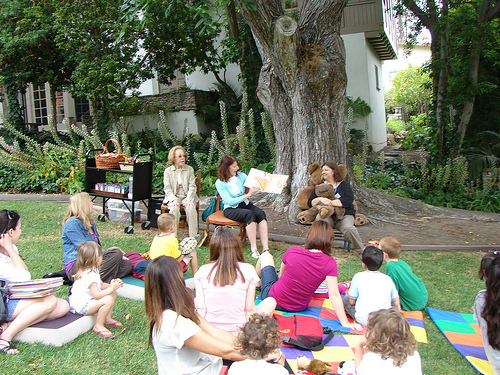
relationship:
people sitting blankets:
[2, 190, 481, 361] [421, 304, 479, 366]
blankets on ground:
[421, 304, 479, 366] [5, 201, 467, 372]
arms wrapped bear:
[304, 192, 354, 212] [295, 164, 338, 245]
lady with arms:
[311, 159, 367, 251] [304, 192, 354, 212]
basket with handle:
[95, 139, 123, 167] [98, 138, 119, 148]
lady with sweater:
[214, 152, 272, 257] [214, 181, 249, 201]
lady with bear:
[313, 165, 366, 245] [316, 185, 332, 221]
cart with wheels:
[82, 148, 154, 234] [94, 216, 164, 237]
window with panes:
[11, 86, 61, 136] [29, 83, 54, 123]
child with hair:
[228, 314, 275, 372] [246, 318, 271, 352]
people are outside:
[4, 147, 445, 370] [3, 4, 484, 367]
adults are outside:
[146, 226, 344, 372] [3, 4, 484, 367]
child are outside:
[228, 314, 292, 374] [3, 4, 484, 367]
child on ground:
[228, 314, 292, 374] [13, 205, 158, 365]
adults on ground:
[3, 180, 133, 312] [39, 209, 145, 372]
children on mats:
[340, 306, 422, 373] [277, 311, 362, 368]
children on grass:
[130, 247, 415, 372] [55, 337, 151, 372]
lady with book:
[203, 156, 283, 252] [241, 169, 296, 208]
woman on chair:
[156, 142, 205, 243] [196, 173, 204, 233]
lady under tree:
[311, 159, 367, 251] [240, 3, 354, 169]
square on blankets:
[424, 310, 458, 325] [421, 304, 500, 374]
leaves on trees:
[5, 4, 228, 92] [0, 1, 267, 167]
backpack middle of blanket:
[270, 313, 335, 352] [254, 283, 427, 374]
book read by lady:
[244, 163, 287, 205] [208, 147, 287, 262]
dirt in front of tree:
[374, 196, 498, 236] [235, 5, 496, 267]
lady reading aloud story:
[214, 152, 272, 257] [240, 167, 289, 199]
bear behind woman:
[303, 155, 349, 226] [307, 159, 367, 240]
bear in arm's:
[318, 181, 347, 224] [307, 195, 348, 206]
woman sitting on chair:
[160, 145, 202, 244] [150, 193, 215, 224]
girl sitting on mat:
[274, 220, 354, 331] [305, 300, 364, 346]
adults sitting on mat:
[192, 225, 280, 336] [270, 310, 300, 323]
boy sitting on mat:
[358, 242, 388, 326] [339, 313, 377, 333]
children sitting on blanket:
[340, 306, 422, 373] [254, 283, 427, 374]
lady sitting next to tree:
[311, 159, 367, 251] [240, 3, 424, 261]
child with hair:
[69, 240, 124, 338] [69, 239, 101, 267]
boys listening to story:
[357, 223, 417, 307] [242, 160, 292, 195]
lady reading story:
[214, 152, 272, 257] [242, 166, 291, 190]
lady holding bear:
[311, 159, 367, 251] [308, 179, 343, 216]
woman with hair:
[0, 206, 83, 344] [0, 202, 19, 229]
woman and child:
[0, 206, 73, 356] [69, 240, 124, 338]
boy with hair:
[145, 211, 199, 276] [154, 209, 176, 230]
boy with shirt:
[145, 211, 199, 276] [142, 230, 188, 258]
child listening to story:
[70, 240, 125, 341] [248, 166, 290, 196]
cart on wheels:
[82, 144, 157, 234] [96, 212, 152, 236]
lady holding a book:
[214, 152, 272, 257] [246, 166, 291, 194]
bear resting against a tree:
[305, 181, 344, 222] [228, 2, 350, 215]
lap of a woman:
[6, 298, 70, 313] [0, 206, 73, 356]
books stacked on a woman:
[13, 275, 62, 295] [0, 206, 73, 356]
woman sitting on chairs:
[160, 145, 202, 244] [156, 210, 338, 245]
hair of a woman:
[306, 220, 335, 240] [270, 224, 361, 337]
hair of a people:
[144, 254, 201, 334] [142, 253, 283, 373]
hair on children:
[237, 310, 425, 364] [229, 310, 425, 372]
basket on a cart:
[95, 139, 129, 171] [87, 159, 156, 235]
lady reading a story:
[214, 152, 272, 257] [243, 167, 288, 194]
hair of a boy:
[362, 243, 384, 272] [343, 245, 401, 324]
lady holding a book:
[214, 152, 272, 257] [248, 167, 290, 199]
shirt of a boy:
[387, 253, 427, 307] [373, 231, 433, 315]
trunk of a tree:
[228, 2, 342, 222] [57, 2, 358, 225]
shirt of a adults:
[60, 215, 100, 262] [43, 189, 131, 286]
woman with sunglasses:
[160, 145, 202, 244] [169, 152, 187, 159]